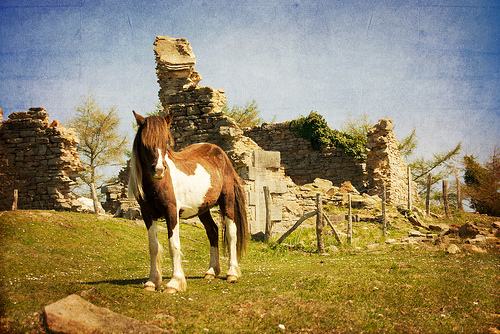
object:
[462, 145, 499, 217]
brown bush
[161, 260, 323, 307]
grass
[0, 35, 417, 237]
building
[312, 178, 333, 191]
rock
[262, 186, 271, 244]
wood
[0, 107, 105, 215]
rock wall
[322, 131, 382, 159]
no sense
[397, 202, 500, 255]
rock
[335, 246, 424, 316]
plant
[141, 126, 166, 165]
face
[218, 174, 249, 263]
tail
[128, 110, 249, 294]
animal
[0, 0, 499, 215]
sky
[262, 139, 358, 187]
rock wall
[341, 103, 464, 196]
tree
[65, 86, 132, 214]
tree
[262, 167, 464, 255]
fence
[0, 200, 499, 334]
field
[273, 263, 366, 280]
leaves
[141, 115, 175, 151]
hair